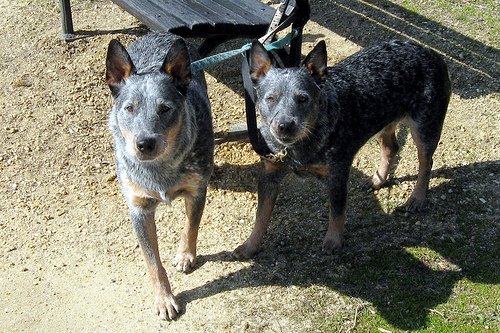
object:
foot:
[171, 251, 199, 272]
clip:
[265, 144, 284, 163]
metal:
[191, 27, 301, 52]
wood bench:
[107, 0, 289, 37]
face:
[110, 67, 185, 160]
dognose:
[279, 115, 298, 136]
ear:
[243, 32, 274, 78]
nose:
[133, 134, 158, 154]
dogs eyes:
[126, 104, 172, 111]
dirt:
[2, 2, 484, 330]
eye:
[262, 86, 277, 107]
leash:
[180, 32, 302, 63]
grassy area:
[258, 196, 498, 331]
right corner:
[328, 241, 499, 328]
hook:
[262, 147, 290, 162]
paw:
[230, 240, 260, 260]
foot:
[228, 221, 268, 262]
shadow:
[221, 182, 497, 310]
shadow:
[180, 163, 497, 331]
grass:
[391, 276, 453, 323]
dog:
[229, 38, 453, 266]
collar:
[274, 141, 298, 163]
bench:
[52, 0, 313, 37]